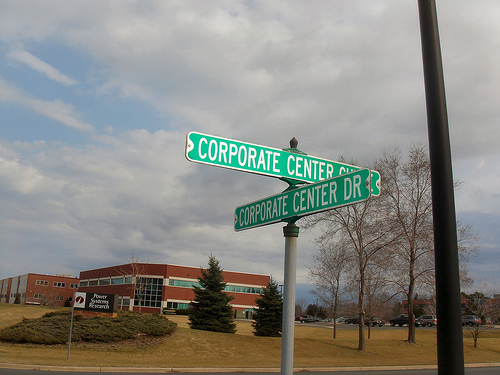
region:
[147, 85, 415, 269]
the signs are green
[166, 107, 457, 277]
the text is white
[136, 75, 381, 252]
the sky is cloudy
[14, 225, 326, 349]
the buildings are brick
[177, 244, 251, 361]
this is a pine tree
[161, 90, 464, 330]
the streets are corporate center drive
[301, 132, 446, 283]
these trees are bare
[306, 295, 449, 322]
a parking lot in distance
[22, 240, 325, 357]
this is an office building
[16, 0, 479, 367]
the season is fall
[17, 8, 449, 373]
green street sign on a pole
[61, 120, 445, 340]
two greens street signs on a pole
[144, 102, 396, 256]
two street signs perpendicular to each other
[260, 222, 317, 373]
street sign pole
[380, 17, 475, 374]
long wooden pole in ground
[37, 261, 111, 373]
pole holding up street sign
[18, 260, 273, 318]
brick building in background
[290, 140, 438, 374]
barren trees on top of grass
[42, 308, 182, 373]
bushes on top of grass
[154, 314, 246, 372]
brown and green grass on ground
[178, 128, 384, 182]
a green street sign.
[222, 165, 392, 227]
a light green street sign.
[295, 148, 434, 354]
a small forest of leafless trees.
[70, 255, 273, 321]
a multi story building.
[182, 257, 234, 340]
a needle filled pine tree.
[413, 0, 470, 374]
a tall pole.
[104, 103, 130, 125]
a section of blue sky.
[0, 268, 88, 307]
a building near a field.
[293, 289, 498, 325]
a forest filled with trees.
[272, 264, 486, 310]
A small mountain range.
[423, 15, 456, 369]
this is a pole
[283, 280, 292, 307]
the pole is white in color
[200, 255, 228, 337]
this is a tree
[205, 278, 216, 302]
the leaves are green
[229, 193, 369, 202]
this is a writing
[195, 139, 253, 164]
the writing is in white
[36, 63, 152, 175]
this is thew sky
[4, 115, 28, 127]
the sky is blue in color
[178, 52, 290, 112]
these are the clouds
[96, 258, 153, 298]
this is a building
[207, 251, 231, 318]
this is a tree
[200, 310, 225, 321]
the leaves are green in color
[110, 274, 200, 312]
this is a building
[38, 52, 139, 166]
this is the sky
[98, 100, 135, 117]
the sky is blue in color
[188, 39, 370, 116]
these are the clouds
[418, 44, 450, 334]
this is a pole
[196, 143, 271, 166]
this is a writing